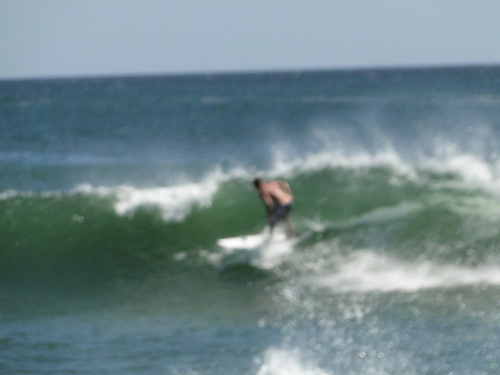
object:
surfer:
[246, 176, 298, 256]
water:
[1, 65, 499, 374]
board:
[210, 226, 297, 254]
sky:
[0, 1, 500, 77]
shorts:
[266, 203, 288, 220]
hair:
[250, 178, 261, 184]